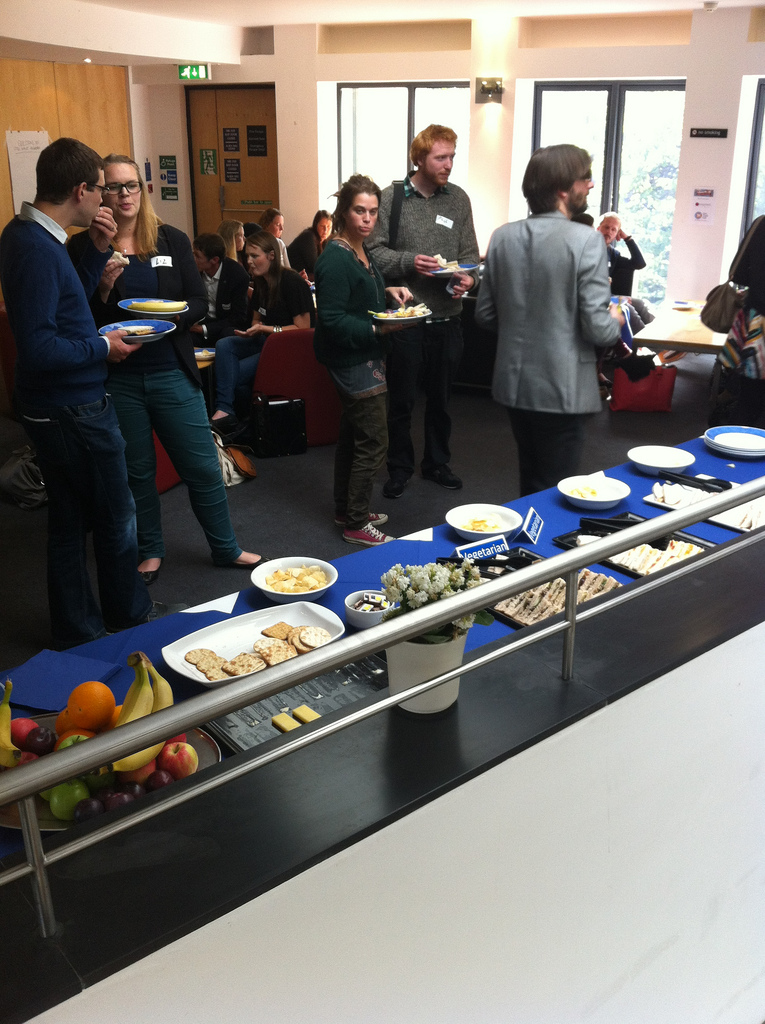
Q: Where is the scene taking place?
A: In a conference room.